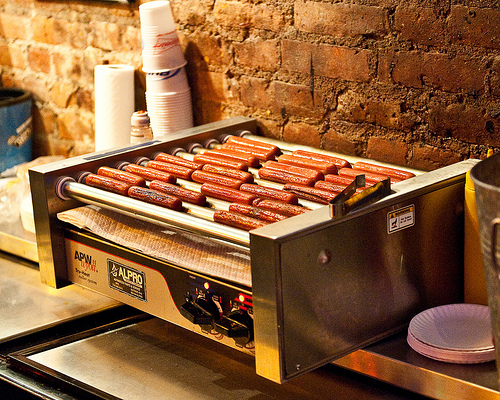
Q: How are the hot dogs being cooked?
A: On a hot dog roller grill.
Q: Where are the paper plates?
A: To the right of the roaster on a counter.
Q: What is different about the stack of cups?
A: The top cup isn't flush with the other cups.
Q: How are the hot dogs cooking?
A: They are being turned constantly on the roller grill.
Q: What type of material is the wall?
A: Brick.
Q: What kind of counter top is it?
A: Stainless Steel.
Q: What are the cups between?
A: A roll of paper towels and the hot dog roller grill.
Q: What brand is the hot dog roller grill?
A: Alpro.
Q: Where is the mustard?
A: To the right of the hot dog roller grill behind the paper plates.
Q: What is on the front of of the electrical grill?
A: The control knobs.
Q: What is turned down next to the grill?
A: The stack of plastic cups.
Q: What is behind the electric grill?
A: The brick wall.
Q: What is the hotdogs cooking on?
A: Hotdog girll.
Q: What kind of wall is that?
A: Brick wall.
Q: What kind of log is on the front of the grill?
A: Black and white.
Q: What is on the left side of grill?
A: Plastic cups.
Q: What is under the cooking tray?
A: Greasy paper towel.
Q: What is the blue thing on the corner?
A: Blue plastic big gulp cup.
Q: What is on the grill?
A: Hot-dogs and sausages.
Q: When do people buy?
A: Compulsive purchase.